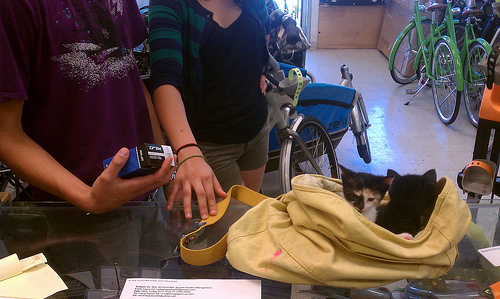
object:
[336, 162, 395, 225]
kitten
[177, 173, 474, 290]
backpack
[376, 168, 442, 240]
kitten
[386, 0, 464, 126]
bicycle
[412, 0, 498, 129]
bicycle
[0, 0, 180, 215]
person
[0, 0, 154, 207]
shirt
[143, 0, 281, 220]
person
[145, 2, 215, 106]
sweater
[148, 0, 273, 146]
shirt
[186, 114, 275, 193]
shorts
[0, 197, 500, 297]
counter top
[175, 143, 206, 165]
wrist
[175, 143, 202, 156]
elastic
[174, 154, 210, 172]
bracelet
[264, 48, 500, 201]
floor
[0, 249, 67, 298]
paper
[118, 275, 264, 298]
paper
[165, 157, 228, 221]
hand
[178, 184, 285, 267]
handle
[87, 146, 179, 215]
hand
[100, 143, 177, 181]
box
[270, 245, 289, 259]
smudge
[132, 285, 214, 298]
writing